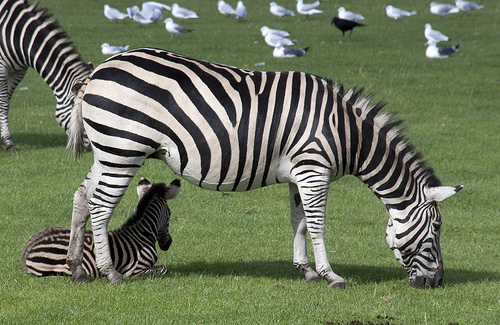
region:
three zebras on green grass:
[1, 0, 448, 305]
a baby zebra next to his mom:
[16, 169, 187, 288]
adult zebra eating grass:
[50, 41, 475, 309]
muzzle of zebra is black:
[397, 258, 452, 295]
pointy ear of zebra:
[420, 168, 473, 208]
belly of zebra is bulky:
[168, 146, 279, 201]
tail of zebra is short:
[58, 58, 92, 165]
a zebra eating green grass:
[1, 2, 108, 169]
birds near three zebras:
[98, 0, 489, 75]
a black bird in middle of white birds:
[246, 3, 448, 58]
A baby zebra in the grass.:
[16, 173, 183, 285]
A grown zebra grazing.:
[62, 43, 455, 298]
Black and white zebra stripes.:
[218, 67, 265, 194]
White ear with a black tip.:
[421, 178, 468, 207]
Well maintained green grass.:
[191, 266, 278, 318]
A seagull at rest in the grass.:
[418, 36, 460, 63]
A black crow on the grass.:
[327, 13, 367, 36]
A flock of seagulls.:
[98, 3, 201, 36]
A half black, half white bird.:
[267, 38, 309, 59]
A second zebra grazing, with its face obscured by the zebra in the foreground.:
[1, 1, 111, 146]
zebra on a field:
[52, 26, 468, 278]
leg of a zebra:
[295, 155, 335, 285]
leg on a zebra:
[285, 195, 310, 280]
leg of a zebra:
[80, 140, 135, 285]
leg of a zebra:
[70, 155, 90, 280]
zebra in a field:
[125, 170, 175, 265]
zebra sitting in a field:
[120, 170, 185, 275]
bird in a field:
[420, 30, 460, 60]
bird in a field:
[315, 10, 360, 35]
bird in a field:
[160, 10, 190, 40]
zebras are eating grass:
[1, 0, 481, 322]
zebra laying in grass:
[8, 154, 200, 284]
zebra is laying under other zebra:
[15, 150, 200, 282]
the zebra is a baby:
[8, 170, 192, 285]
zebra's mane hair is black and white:
[336, 77, 464, 196]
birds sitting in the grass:
[85, 0, 485, 100]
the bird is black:
[320, 5, 367, 48]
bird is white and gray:
[423, 33, 455, 60]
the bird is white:
[171, 5, 197, 21]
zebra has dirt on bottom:
[19, 210, 71, 285]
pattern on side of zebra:
[197, 89, 292, 151]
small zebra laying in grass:
[13, 178, 203, 291]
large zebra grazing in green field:
[274, 86, 473, 298]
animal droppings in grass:
[325, 308, 397, 323]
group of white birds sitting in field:
[207, 0, 324, 61]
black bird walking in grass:
[321, 15, 364, 42]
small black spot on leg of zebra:
[286, 190, 306, 212]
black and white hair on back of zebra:
[368, 97, 466, 185]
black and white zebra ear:
[420, 179, 470, 206]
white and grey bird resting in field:
[424, 39, 468, 61]